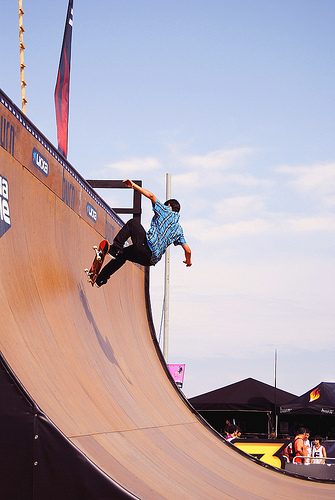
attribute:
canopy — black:
[218, 387, 262, 399]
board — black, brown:
[81, 241, 110, 286]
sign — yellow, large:
[234, 432, 284, 473]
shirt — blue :
[145, 194, 186, 258]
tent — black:
[177, 368, 303, 447]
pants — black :
[98, 218, 151, 282]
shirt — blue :
[144, 200, 188, 262]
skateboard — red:
[84, 239, 108, 284]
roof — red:
[188, 375, 302, 408]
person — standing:
[289, 426, 307, 463]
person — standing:
[301, 430, 311, 464]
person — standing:
[308, 434, 326, 463]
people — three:
[280, 423, 322, 471]